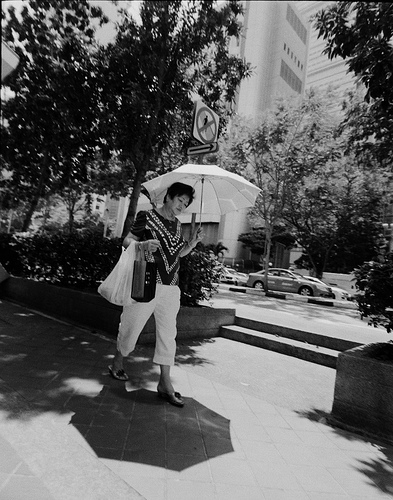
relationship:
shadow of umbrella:
[148, 137, 272, 239] [138, 140, 277, 231]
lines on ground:
[70, 400, 135, 495] [43, 395, 149, 497]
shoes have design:
[97, 348, 195, 414] [169, 374, 187, 403]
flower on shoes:
[165, 382, 194, 401] [97, 348, 195, 414]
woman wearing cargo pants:
[85, 173, 206, 429] [108, 261, 213, 371]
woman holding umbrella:
[85, 173, 206, 429] [138, 140, 277, 231]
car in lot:
[231, 245, 347, 310] [205, 232, 392, 355]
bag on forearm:
[105, 239, 177, 309] [116, 231, 181, 259]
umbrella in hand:
[138, 140, 277, 231] [185, 218, 213, 241]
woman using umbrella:
[85, 173, 206, 429] [138, 140, 277, 231]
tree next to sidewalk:
[89, 1, 252, 268] [205, 232, 392, 355]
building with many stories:
[207, 4, 387, 206] [264, 24, 326, 103]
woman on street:
[85, 173, 206, 429] [5, 296, 389, 500]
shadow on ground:
[148, 137, 272, 239] [5, 296, 389, 500]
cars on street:
[231, 245, 347, 310] [5, 296, 389, 500]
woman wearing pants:
[85, 173, 206, 429] [108, 261, 213, 371]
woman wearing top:
[85, 173, 206, 429] [125, 212, 220, 284]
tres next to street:
[89, 1, 252, 268] [5, 296, 389, 500]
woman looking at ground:
[85, 173, 206, 429] [43, 395, 149, 497]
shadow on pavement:
[148, 137, 272, 239] [5, 296, 389, 500]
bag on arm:
[105, 239, 177, 309] [122, 218, 166, 262]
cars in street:
[231, 245, 347, 310] [5, 296, 389, 500]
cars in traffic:
[231, 245, 347, 310] [205, 232, 392, 355]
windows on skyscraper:
[260, 59, 323, 99] [207, 4, 387, 206]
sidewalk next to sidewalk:
[221, 286, 382, 347] [221, 286, 382, 347]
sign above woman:
[180, 90, 256, 155] [85, 173, 206, 429]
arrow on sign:
[185, 127, 232, 161] [180, 90, 256, 155]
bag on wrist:
[105, 239, 177, 309] [141, 238, 173, 259]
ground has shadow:
[43, 395, 149, 497] [148, 137, 272, 239]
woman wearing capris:
[85, 173, 206, 429] [108, 261, 213, 371]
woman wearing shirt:
[85, 173, 206, 429] [125, 212, 220, 284]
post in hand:
[185, 200, 222, 239] [185, 218, 213, 241]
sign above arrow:
[180, 90, 256, 155] [185, 127, 232, 161]